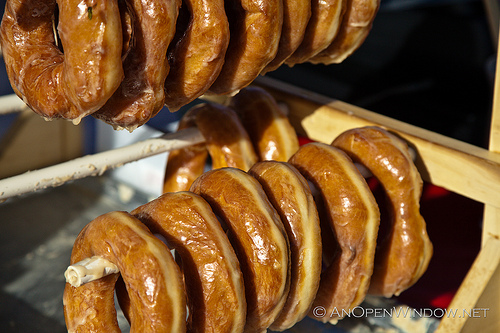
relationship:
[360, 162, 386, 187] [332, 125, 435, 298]
edge of cake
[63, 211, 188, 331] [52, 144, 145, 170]
donut on a stick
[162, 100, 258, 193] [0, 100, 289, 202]
donut on middle stick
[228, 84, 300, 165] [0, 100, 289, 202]
donut on middle stick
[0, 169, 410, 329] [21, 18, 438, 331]
gray surface under donuts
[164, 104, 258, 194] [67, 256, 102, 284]
donut hanging on stick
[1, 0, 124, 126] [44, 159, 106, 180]
donut in rods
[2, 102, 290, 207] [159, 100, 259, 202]
rod holding donut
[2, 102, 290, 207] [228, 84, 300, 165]
rod holding donut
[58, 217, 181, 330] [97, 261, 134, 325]
donut has hole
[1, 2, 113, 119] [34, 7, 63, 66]
donut has hole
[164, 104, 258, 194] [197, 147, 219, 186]
donut has hole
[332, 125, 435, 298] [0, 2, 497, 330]
cake on a rack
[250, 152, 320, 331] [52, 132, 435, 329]
donut on a rack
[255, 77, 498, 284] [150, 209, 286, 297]
box holding donut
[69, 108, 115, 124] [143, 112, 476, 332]
glaze dripping off of donuts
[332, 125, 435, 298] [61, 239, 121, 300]
cake on a rack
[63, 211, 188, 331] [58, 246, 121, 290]
donut on a rack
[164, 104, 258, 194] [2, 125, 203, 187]
donut on a dowel